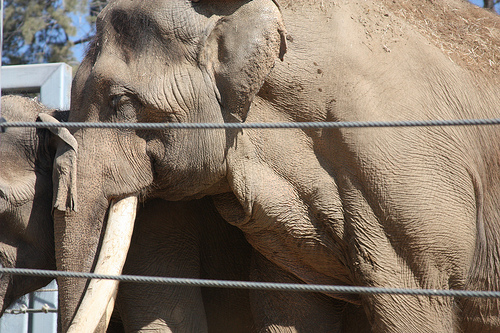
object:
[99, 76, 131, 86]
eyebrows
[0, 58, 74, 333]
door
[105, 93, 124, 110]
closed eye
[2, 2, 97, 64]
sky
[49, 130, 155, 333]
brown trunk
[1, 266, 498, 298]
wire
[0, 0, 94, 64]
trees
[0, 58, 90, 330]
buildings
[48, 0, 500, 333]
elephant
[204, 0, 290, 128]
ear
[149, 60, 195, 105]
wrinkle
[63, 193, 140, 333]
elephant tusk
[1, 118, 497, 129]
retaining wire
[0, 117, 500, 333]
elephant stockade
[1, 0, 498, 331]
pen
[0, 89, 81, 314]
elephant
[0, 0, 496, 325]
enclosure